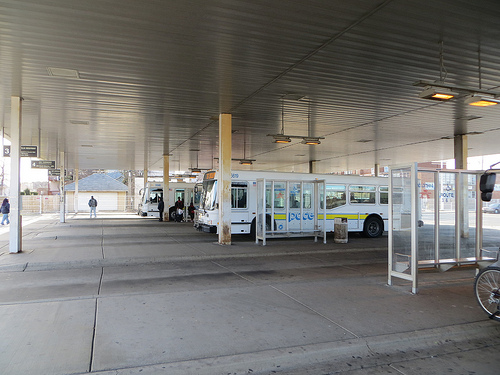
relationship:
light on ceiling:
[422, 85, 457, 110] [2, 0, 484, 174]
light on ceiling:
[298, 129, 323, 150] [2, 0, 484, 174]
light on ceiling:
[239, 160, 253, 165] [2, 0, 484, 174]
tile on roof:
[3, 11, 269, 103] [66, 175, 141, 196]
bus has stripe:
[204, 162, 430, 244] [266, 210, 372, 224]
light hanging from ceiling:
[269, 132, 293, 152] [305, 47, 420, 79]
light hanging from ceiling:
[297, 134, 322, 152] [305, 47, 420, 79]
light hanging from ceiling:
[432, 93, 454, 100] [305, 47, 420, 79]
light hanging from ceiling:
[232, 156, 260, 172] [305, 47, 420, 79]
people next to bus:
[157, 197, 164, 222] [195, 169, 424, 252]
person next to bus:
[169, 192, 189, 222] [195, 169, 424, 252]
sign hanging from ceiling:
[29, 157, 61, 173] [2, 0, 484, 174]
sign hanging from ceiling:
[2, 141, 42, 161] [2, 0, 484, 174]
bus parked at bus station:
[193, 169, 424, 240] [2, 2, 479, 373]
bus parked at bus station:
[131, 176, 205, 227] [2, 2, 479, 373]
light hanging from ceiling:
[268, 133, 326, 153] [2, 0, 484, 174]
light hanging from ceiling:
[239, 160, 253, 165] [2, 0, 484, 174]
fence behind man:
[10, 188, 146, 218] [88, 196, 98, 219]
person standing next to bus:
[169, 192, 189, 222] [196, 164, 467, 226]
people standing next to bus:
[157, 197, 164, 222] [196, 164, 467, 226]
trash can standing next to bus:
[330, 215, 350, 246] [195, 167, 424, 236]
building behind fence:
[67, 169, 132, 216] [21, 193, 137, 218]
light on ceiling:
[432, 93, 454, 100] [6, 2, 494, 160]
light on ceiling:
[468, 93, 491, 111] [6, 2, 494, 160]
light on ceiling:
[300, 137, 322, 146] [6, 2, 494, 160]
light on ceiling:
[239, 160, 253, 165] [6, 2, 494, 160]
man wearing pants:
[80, 195, 115, 224] [88, 205, 102, 217]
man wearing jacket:
[0, 198, 9, 225] [0, 202, 10, 214]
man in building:
[88, 196, 98, 219] [5, 5, 497, 365]